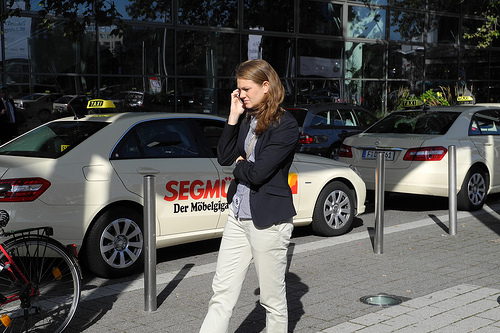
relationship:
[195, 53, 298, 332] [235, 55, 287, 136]
woman has hair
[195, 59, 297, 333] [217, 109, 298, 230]
woman wearing blazer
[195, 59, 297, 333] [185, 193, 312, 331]
woman wearing pants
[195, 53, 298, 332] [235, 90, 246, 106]
woman on cell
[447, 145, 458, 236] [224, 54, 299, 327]
poles behind woman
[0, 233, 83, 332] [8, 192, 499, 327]
tire on sidewalk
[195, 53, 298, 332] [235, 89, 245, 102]
woman on cell phone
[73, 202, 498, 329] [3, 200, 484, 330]
concrete on sidewalk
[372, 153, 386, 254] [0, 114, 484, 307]
pole line street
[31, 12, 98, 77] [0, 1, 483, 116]
window on building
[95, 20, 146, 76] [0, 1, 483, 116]
window on building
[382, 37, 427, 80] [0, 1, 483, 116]
window on building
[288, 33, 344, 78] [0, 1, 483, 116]
window on building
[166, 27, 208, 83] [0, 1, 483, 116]
window on building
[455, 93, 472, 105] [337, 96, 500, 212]
sign on cars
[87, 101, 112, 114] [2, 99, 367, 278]
sign on car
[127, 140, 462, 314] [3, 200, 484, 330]
poles on sidewalk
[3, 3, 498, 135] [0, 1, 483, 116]
windows on building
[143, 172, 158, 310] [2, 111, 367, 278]
pole by car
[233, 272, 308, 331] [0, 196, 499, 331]
shadow on ground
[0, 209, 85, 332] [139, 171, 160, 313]
bicycle in front of pole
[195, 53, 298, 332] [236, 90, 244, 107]
woman on cell phone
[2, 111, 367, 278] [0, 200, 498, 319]
car on curb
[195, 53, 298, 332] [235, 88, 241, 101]
woman on phone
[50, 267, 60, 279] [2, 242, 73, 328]
reflector on spokes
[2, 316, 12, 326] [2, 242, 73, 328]
reflector on spokes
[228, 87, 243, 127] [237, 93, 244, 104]
hand holding cell phone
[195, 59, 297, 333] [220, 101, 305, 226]
woman wearing blazer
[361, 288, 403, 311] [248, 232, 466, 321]
light on ground